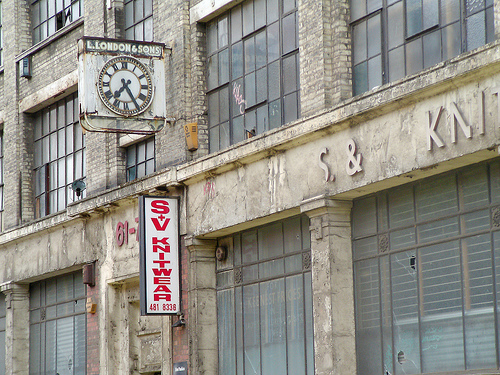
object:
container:
[183, 122, 198, 151]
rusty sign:
[77, 35, 165, 58]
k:
[425, 105, 445, 150]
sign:
[138, 196, 182, 317]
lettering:
[149, 200, 172, 302]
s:
[318, 147, 330, 182]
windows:
[209, 124, 220, 155]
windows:
[28, 280, 40, 309]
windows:
[240, 229, 258, 265]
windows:
[350, 195, 379, 241]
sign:
[115, 217, 141, 247]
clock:
[76, 36, 165, 135]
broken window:
[52, 10, 64, 32]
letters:
[159, 253, 164, 260]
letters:
[478, 91, 487, 136]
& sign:
[345, 138, 365, 176]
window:
[229, 77, 245, 119]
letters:
[239, 104, 244, 116]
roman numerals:
[123, 102, 129, 110]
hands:
[120, 78, 140, 111]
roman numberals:
[121, 61, 128, 69]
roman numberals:
[133, 65, 137, 73]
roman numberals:
[138, 74, 145, 80]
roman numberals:
[140, 84, 148, 89]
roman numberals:
[138, 92, 147, 101]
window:
[352, 255, 384, 375]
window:
[388, 180, 415, 231]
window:
[415, 236, 466, 374]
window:
[458, 164, 490, 215]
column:
[0, 280, 31, 375]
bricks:
[330, 79, 353, 89]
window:
[386, 247, 423, 375]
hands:
[113, 79, 131, 98]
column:
[295, 199, 356, 374]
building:
[0, 0, 499, 375]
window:
[206, 19, 218, 55]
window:
[216, 13, 229, 50]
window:
[217, 47, 231, 87]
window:
[228, 40, 245, 81]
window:
[242, 36, 256, 75]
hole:
[409, 255, 417, 271]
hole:
[397, 350, 406, 365]